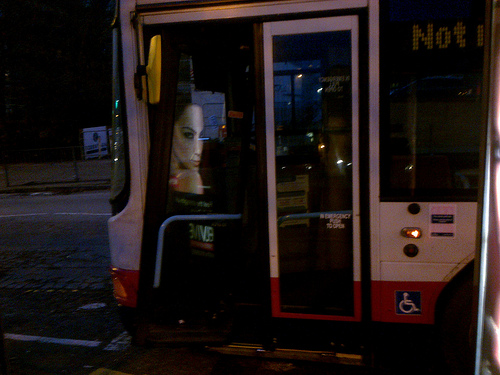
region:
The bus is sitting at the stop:
[87, 11, 499, 367]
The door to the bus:
[142, 3, 369, 333]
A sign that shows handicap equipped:
[384, 280, 433, 325]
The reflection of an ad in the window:
[169, 90, 233, 267]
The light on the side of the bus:
[396, 225, 431, 238]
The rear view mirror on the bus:
[126, 27, 168, 109]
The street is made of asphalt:
[16, 213, 79, 318]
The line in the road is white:
[8, 325, 102, 350]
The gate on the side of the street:
[8, 130, 108, 186]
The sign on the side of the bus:
[384, 6, 496, 70]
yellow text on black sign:
[402, 13, 467, 54]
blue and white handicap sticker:
[395, 287, 417, 315]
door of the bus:
[261, 17, 361, 312]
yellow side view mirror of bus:
[130, 30, 170, 109]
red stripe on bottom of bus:
[112, 269, 436, 324]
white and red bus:
[106, 4, 470, 324]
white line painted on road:
[7, 322, 89, 357]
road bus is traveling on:
[7, 184, 127, 346]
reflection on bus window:
[148, 29, 342, 309]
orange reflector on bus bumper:
[108, 274, 129, 316]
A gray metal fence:
[1, 143, 108, 187]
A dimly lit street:
[4, 192, 311, 372]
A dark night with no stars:
[5, 0, 112, 157]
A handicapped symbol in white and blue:
[397, 291, 421, 312]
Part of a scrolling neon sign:
[412, 23, 494, 49]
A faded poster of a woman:
[163, 83, 233, 258]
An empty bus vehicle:
[107, 0, 485, 374]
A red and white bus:
[108, 0, 480, 353]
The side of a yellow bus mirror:
[137, 36, 162, 106]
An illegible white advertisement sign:
[79, 126, 126, 160]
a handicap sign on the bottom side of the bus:
[393, 290, 422, 316]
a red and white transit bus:
[105, 1, 474, 373]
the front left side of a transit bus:
[106, 3, 470, 344]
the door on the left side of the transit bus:
[260, 13, 364, 323]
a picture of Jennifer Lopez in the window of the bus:
[165, 96, 201, 191]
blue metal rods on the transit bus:
[153, 208, 350, 288]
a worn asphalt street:
[1, 194, 101, 374]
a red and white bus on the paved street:
[6, 1, 482, 373]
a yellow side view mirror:
[143, 35, 163, 105]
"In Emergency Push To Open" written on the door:
[317, 212, 350, 229]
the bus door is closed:
[229, 11, 376, 362]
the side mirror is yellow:
[137, 29, 180, 123]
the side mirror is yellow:
[113, 34, 193, 143]